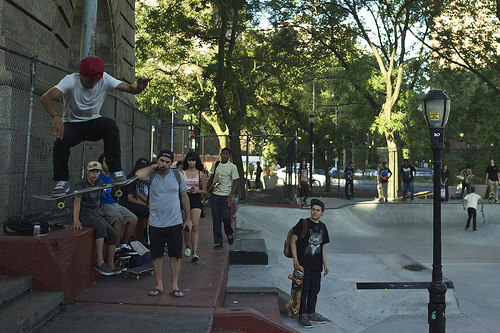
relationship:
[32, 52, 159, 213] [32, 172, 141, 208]
boy with skateboard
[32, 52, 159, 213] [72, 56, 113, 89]
boy wearing cap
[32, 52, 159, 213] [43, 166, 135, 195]
boy wearing sneakers